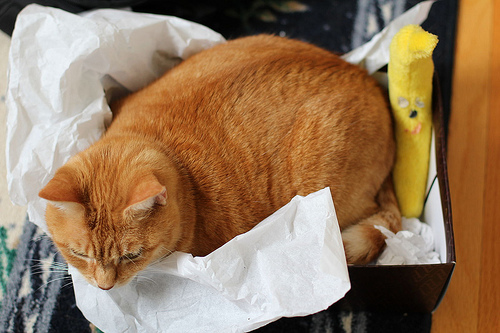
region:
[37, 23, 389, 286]
orange cat in shoe box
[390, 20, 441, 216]
yellow stuffed toy banana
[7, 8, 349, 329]
white paperi n shoe box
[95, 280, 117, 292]
black nose of cat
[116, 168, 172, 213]
ear on cat's head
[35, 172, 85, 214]
ear on cat's head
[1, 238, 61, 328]
blue and white rug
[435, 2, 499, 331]
light brown wood post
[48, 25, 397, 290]
cat sleeping in box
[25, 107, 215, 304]
head of a cat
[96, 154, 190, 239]
ear of a cat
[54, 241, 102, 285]
eye of a cat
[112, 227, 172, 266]
eye of a cat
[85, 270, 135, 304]
nose of a cat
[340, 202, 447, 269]
tail of a cat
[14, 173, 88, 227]
an ear of a cat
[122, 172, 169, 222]
one left orange and white cat ear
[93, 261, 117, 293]
top view of one cat nose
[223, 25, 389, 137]
one orange cat backside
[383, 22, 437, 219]
one little plush banana cat toy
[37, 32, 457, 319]
one cat in a box with toy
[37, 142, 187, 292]
one orange cat head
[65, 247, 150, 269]
two cat eyes looking down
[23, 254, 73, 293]
group of white cat whiskers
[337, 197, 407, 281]
cat tail curled next to tissue paper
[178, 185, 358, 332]
section of white tissue paper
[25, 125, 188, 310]
head of a cat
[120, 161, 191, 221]
ear of a cat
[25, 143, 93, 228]
an ear of a cat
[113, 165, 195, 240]
an ear of a cat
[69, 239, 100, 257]
eye of a cat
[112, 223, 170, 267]
eye of a cat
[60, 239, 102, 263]
an eye of a cat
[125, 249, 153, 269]
an eye of a cat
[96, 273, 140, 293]
a nose of a cat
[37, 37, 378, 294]
brown cat in box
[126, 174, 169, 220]
left ear on cat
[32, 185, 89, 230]
right ear on cat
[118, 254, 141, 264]
the cat's left eye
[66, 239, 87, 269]
the cat's right eye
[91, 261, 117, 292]
nose of the cat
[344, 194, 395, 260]
the tail of the cat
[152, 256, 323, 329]
white tissue paper in box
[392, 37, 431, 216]
yellow puppet in box